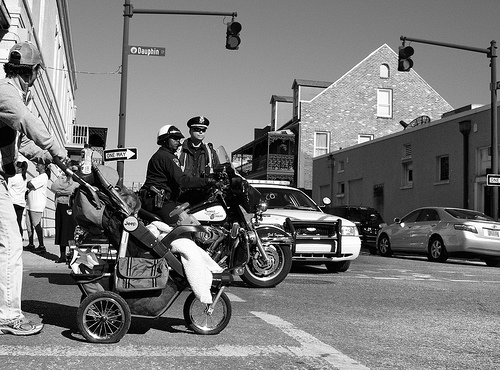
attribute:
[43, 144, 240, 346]
stroller — existing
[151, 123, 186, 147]
helmet — white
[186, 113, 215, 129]
hat — black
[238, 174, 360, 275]
car — police car, white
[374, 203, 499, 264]
car — parked, silver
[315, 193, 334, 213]
mirror — side view mirror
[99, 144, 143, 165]
sign — one way, street sign, one way sign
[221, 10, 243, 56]
lights — traffic lights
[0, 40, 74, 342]
person — standing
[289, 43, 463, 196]
building — brick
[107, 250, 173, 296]
bag — small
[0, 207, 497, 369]
street — named